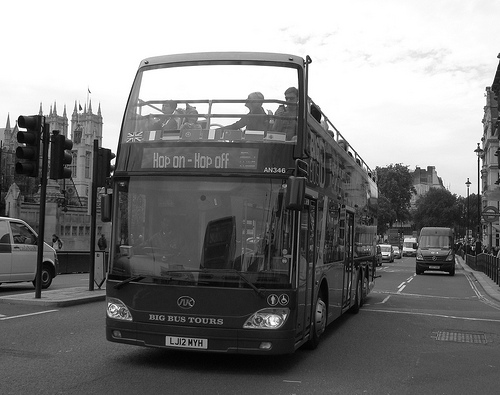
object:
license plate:
[163, 333, 212, 349]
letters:
[164, 336, 180, 349]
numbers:
[176, 337, 185, 347]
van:
[0, 218, 57, 290]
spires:
[48, 85, 106, 127]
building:
[0, 97, 108, 253]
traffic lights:
[14, 113, 74, 183]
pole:
[31, 167, 53, 300]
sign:
[149, 152, 232, 171]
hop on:
[152, 152, 185, 170]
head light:
[239, 306, 289, 331]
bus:
[94, 50, 382, 364]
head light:
[100, 297, 134, 323]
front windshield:
[115, 164, 289, 295]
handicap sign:
[275, 293, 290, 308]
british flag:
[125, 130, 140, 144]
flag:
[86, 86, 93, 98]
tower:
[72, 87, 105, 208]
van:
[413, 223, 458, 273]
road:
[310, 262, 496, 382]